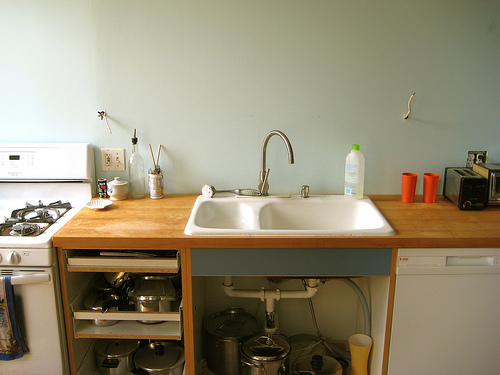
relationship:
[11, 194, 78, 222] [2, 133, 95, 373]
burner on gas stove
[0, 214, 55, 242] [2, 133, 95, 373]
burner on gas stove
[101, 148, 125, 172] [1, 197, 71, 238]
outlet near stove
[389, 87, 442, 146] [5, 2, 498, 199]
wire hanging out wall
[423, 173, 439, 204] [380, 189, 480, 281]
cup on counter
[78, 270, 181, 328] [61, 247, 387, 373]
pots in cabinet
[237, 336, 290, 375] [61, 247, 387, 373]
pots in cabinet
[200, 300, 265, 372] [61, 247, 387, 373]
pots in cabinet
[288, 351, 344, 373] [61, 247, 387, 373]
pots in cabinet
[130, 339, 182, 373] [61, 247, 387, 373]
pots in cabinet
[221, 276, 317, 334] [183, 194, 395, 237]
pipe under kitchen sink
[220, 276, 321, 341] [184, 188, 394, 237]
pipe for sink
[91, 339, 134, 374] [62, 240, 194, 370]
pot in cabinet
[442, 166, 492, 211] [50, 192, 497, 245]
toaster on counter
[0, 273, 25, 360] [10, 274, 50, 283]
towel on handle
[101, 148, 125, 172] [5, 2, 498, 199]
outlet on wall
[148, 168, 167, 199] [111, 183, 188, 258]
container on counter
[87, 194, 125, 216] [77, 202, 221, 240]
small dish on counter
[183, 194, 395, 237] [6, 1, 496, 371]
kitchen sink in kitchen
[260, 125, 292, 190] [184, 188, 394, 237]
faucet of sink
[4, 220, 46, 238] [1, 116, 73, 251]
burner on stove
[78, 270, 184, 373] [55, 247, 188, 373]
pots in cabinet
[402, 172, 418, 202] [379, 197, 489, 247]
cup on counter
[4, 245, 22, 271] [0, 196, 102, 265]
knob on counter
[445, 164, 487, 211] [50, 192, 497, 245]
toaster on counter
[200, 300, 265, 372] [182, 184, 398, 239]
pots under sink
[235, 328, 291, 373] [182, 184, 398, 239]
pots under sink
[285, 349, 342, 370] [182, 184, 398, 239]
pots under sink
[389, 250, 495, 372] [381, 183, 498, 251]
dishwasher built into counter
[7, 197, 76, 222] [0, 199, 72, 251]
burner on stove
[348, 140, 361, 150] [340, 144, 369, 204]
cap on bottle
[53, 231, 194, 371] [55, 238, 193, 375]
cabinet has cabinet